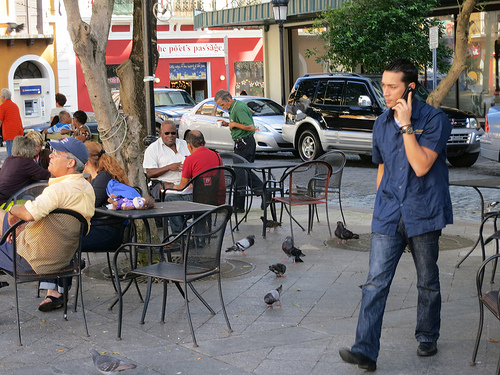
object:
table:
[223, 152, 310, 243]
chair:
[261, 159, 334, 247]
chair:
[280, 149, 348, 228]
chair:
[213, 150, 272, 232]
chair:
[161, 165, 238, 245]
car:
[278, 72, 484, 166]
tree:
[314, 2, 439, 90]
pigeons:
[223, 234, 256, 257]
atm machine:
[21, 84, 42, 118]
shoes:
[338, 344, 379, 373]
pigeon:
[333, 221, 359, 245]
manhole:
[322, 222, 478, 254]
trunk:
[103, 175, 145, 215]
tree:
[61, 0, 161, 283]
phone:
[397, 86, 414, 107]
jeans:
[347, 223, 444, 358]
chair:
[109, 204, 240, 349]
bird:
[225, 234, 256, 256]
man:
[212, 87, 272, 213]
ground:
[0, 140, 499, 373]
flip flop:
[39, 292, 67, 313]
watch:
[399, 126, 413, 134]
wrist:
[397, 126, 418, 135]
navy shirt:
[369, 100, 454, 238]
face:
[381, 70, 405, 108]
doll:
[106, 194, 156, 211]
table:
[89, 191, 231, 328]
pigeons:
[259, 216, 284, 233]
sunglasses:
[162, 130, 178, 136]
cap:
[46, 136, 90, 164]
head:
[45, 148, 85, 174]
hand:
[392, 91, 413, 126]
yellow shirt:
[22, 173, 98, 245]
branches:
[301, 0, 457, 76]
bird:
[262, 284, 286, 309]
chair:
[1, 207, 95, 348]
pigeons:
[281, 235, 305, 264]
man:
[142, 121, 193, 198]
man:
[165, 130, 222, 247]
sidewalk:
[218, 200, 377, 367]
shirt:
[181, 146, 232, 194]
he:
[337, 57, 457, 371]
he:
[0, 133, 98, 314]